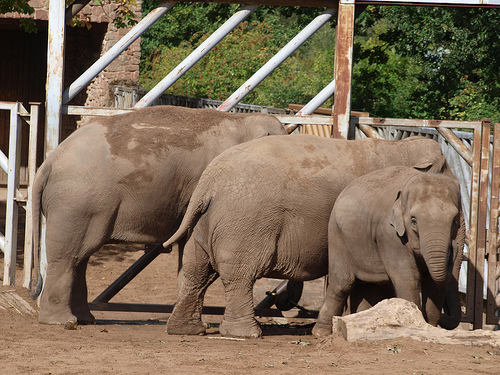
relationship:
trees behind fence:
[146, 5, 488, 111] [1, 109, 56, 299]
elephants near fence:
[25, 127, 486, 332] [1, 109, 56, 299]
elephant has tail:
[21, 105, 318, 323] [23, 171, 60, 299]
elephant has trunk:
[321, 161, 482, 342] [420, 221, 446, 283]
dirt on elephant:
[88, 97, 223, 160] [21, 105, 318, 323]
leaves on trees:
[347, 9, 462, 120] [146, 5, 488, 111]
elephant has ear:
[321, 161, 482, 342] [448, 187, 465, 234]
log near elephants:
[314, 304, 495, 360] [25, 127, 486, 332]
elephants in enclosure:
[25, 127, 486, 332] [4, 8, 493, 313]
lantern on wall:
[90, 4, 144, 65] [7, 7, 141, 121]